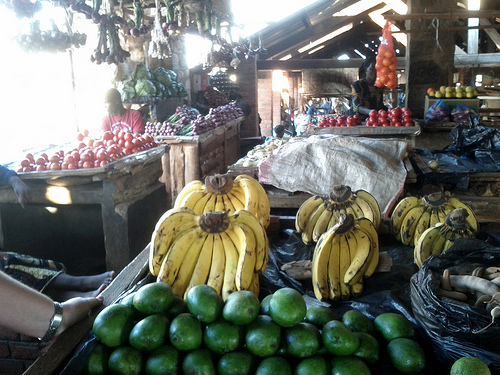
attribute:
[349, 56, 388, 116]
buyer — prospective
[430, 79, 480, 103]
apples — jumbo, golden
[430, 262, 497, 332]
items — edible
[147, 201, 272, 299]
bananas — two bunches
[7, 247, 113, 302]
legs — crossed, resting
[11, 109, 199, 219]
crate — grey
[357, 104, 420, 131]
apples — stacked together, red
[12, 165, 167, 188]
bin — big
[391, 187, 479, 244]
banans — in a bunch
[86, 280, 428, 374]
avocados — in a pyramid, for sale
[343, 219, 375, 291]
bananas — on a cart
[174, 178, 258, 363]
fruit — stacked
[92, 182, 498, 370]
produce — market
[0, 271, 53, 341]
arm — human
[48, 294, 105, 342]
hand — human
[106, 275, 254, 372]
fruit — in a stack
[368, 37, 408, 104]
oranges — a bag, on display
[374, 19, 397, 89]
bag — orange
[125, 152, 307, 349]
bananas — for sale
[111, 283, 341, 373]
limes — green, stacked up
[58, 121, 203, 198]
apples — red, stacked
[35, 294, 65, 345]
watch — silver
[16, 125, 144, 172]
tomatoes — red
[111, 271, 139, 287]
shelf — wood